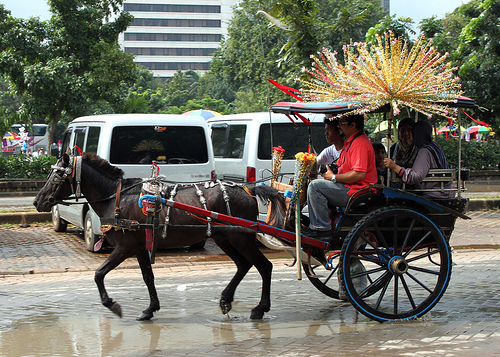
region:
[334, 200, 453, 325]
A big round wheel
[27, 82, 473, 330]
Horse pulling a carriage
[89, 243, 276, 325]
Four legs of a horse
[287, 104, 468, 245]
People sitting in a carriage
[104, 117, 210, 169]
Window on back of vehicle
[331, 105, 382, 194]
Man wearing a red shirt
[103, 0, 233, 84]
A tall white building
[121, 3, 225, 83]
Many windows on a building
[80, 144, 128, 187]
Mane of the horse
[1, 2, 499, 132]
Green trees in the background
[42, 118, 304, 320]
the horse is brown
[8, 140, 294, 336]
the horse is walking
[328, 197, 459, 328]
the wheel is black and blue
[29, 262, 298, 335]
the horse is walking in water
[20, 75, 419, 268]
the cars are parked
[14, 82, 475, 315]
the horse is pulling a buggy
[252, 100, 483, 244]
people are riding in the buggy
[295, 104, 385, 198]
the man on the right is wearing a red shirt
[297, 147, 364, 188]
man is holding a camera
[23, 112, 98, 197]
the horse is wearing a headdress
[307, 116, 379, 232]
sitting man in red shirt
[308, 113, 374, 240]
sitting man holding a camera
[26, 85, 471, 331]
horse pulling carriage of people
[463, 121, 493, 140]
multicolored unbrella for shade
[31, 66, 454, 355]
horse pulling carriage in water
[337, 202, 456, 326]
wagon wheel with blue trim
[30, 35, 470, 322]
horse drawn carriage with four people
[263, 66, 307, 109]
two waving red streamers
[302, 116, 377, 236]
man with gray pants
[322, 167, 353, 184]
forearm and hand with watch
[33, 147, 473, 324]
the horse pulling the small carriage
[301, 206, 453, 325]
the wheels on the carriage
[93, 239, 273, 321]
the horse's four legs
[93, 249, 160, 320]
the horse's front legs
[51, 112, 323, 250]
the two vehicles parked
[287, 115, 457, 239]
the people in the carriage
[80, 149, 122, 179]
the mane on the horse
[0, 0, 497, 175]
the trees behind the horse and carriage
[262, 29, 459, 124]
the decorations attached to the carriage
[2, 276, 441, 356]
the puddle of water on the ground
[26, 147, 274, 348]
This is a horse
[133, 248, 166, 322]
Leg of a horse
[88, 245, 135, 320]
Leg of a horse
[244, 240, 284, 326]
Leg of a horse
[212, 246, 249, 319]
Leg of a horse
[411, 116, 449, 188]
This is a person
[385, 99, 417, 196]
This is a person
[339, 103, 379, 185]
This is a person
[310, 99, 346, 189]
This is a person